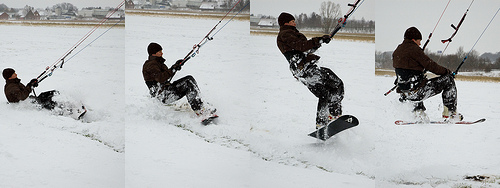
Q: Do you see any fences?
A: No, there are no fences.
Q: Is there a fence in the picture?
A: No, there are no fences.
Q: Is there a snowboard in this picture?
A: Yes, there is a snowboard.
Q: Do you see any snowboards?
A: Yes, there is a snowboard.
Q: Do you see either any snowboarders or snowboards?
A: Yes, there is a snowboard.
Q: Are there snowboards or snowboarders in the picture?
A: Yes, there is a snowboard.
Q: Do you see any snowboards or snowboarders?
A: Yes, there is a snowboard.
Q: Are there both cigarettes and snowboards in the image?
A: No, there is a snowboard but no cigarettes.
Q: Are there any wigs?
A: No, there are no wigs.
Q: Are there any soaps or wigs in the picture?
A: No, there are no wigs or soaps.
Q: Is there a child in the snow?
A: No, there is a snowboard in the snow.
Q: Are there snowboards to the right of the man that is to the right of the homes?
A: Yes, there is a snowboard to the right of the man.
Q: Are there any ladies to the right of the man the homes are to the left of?
A: No, there is a snowboard to the right of the man.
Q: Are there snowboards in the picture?
A: Yes, there is a snowboard.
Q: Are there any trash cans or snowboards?
A: Yes, there is a snowboard.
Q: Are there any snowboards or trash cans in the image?
A: Yes, there is a snowboard.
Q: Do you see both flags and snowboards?
A: No, there is a snowboard but no flags.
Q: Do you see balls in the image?
A: No, there are no balls.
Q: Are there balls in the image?
A: No, there are no balls.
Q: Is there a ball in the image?
A: No, there are no balls.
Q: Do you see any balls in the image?
A: No, there are no balls.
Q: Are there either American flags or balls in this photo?
A: No, there are no balls or American flags.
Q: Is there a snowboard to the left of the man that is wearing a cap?
A: Yes, there is a snowboard to the left of the man.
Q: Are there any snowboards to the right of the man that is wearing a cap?
A: No, the snowboard is to the left of the man.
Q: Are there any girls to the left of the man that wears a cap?
A: No, there is a snowboard to the left of the man.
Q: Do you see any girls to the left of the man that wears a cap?
A: No, there is a snowboard to the left of the man.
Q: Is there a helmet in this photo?
A: No, there are no helmets.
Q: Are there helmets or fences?
A: No, there are no helmets or fences.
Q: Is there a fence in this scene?
A: No, there are no fences.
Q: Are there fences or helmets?
A: No, there are no fences or helmets.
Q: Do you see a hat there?
A: Yes, there is a hat.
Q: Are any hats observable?
A: Yes, there is a hat.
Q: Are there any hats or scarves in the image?
A: Yes, there is a hat.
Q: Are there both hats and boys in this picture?
A: No, there is a hat but no boys.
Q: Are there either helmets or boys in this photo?
A: No, there are no boys or helmets.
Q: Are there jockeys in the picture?
A: No, there are no jockeys.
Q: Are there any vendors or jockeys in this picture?
A: No, there are no jockeys or vendors.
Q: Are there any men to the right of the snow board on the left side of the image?
A: Yes, there is a man to the right of the snowboard.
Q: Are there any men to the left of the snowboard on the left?
A: No, the man is to the right of the snow board.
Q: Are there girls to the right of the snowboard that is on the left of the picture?
A: No, there is a man to the right of the snowboard.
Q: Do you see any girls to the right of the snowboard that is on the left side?
A: No, there is a man to the right of the snowboard.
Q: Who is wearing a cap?
A: The man is wearing a cap.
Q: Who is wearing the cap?
A: The man is wearing a cap.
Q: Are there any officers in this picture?
A: No, there are no officers.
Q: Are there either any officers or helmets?
A: No, there are no officers or helmets.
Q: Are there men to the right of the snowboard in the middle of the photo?
A: Yes, there is a man to the right of the snowboard.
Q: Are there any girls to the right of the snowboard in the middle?
A: No, there is a man to the right of the snowboard.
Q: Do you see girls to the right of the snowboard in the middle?
A: No, there is a man to the right of the snowboard.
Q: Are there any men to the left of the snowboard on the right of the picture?
A: Yes, there is a man to the left of the snow board.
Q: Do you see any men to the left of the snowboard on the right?
A: Yes, there is a man to the left of the snow board.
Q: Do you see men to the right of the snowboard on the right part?
A: No, the man is to the left of the snowboard.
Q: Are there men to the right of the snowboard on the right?
A: No, the man is to the left of the snowboard.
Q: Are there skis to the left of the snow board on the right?
A: No, there is a man to the left of the snowboard.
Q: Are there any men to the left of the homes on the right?
A: Yes, there is a man to the left of the homes.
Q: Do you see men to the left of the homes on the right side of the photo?
A: Yes, there is a man to the left of the homes.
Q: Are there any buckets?
A: No, there are no buckets.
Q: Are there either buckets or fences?
A: No, there are no buckets or fences.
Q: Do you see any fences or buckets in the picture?
A: No, there are no buckets or fences.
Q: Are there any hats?
A: Yes, there is a hat.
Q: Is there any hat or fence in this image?
A: Yes, there is a hat.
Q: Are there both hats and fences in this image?
A: No, there is a hat but no fences.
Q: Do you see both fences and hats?
A: No, there is a hat but no fences.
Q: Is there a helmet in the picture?
A: No, there are no helmets.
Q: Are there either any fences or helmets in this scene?
A: No, there are no helmets or fences.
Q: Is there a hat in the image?
A: Yes, there is a hat.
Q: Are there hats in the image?
A: Yes, there is a hat.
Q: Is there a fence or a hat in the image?
A: Yes, there is a hat.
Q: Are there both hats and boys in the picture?
A: No, there is a hat but no boys.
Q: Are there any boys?
A: No, there are no boys.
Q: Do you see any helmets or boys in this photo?
A: No, there are no boys or helmets.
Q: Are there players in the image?
A: No, there are no players.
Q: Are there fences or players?
A: No, there are no players or fences.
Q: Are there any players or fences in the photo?
A: No, there are no players or fences.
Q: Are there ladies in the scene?
A: No, there are no ladies.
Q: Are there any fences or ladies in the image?
A: No, there are no ladies or fences.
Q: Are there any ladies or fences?
A: No, there are no ladies or fences.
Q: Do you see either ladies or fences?
A: No, there are no ladies or fences.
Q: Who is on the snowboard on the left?
A: The man is on the snowboard.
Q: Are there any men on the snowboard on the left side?
A: Yes, there is a man on the snowboard.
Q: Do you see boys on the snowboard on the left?
A: No, there is a man on the snowboard.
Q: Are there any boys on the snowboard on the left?
A: No, there is a man on the snowboard.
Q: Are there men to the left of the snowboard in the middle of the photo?
A: Yes, there is a man to the left of the snowboard.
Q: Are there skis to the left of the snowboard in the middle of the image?
A: No, there is a man to the left of the snowboard.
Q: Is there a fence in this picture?
A: No, there are no fences.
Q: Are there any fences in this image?
A: No, there are no fences.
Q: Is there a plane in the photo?
A: No, there are no airplanes.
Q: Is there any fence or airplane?
A: No, there are no airplanes or fences.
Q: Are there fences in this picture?
A: No, there are no fences.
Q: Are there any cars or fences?
A: No, there are no fences or cars.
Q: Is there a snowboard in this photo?
A: Yes, there is a snowboard.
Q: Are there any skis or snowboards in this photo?
A: Yes, there is a snowboard.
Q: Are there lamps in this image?
A: No, there are no lamps.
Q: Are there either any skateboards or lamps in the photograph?
A: No, there are no lamps or skateboards.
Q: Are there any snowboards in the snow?
A: Yes, there is a snowboard in the snow.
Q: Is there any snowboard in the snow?
A: Yes, there is a snowboard in the snow.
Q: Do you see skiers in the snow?
A: No, there is a snowboard in the snow.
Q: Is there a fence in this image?
A: No, there are no fences.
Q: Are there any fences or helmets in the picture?
A: No, there are no fences or helmets.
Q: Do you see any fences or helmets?
A: No, there are no fences or helmets.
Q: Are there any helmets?
A: No, there are no helmets.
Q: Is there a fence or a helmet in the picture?
A: No, there are no helmets or fences.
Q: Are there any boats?
A: No, there are no boats.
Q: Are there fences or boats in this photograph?
A: No, there are no boats or fences.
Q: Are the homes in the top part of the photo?
A: Yes, the homes are in the top of the image.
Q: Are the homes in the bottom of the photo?
A: No, the homes are in the top of the image.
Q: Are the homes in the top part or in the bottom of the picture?
A: The homes are in the top of the image.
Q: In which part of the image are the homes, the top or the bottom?
A: The homes are in the top of the image.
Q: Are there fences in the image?
A: No, there are no fences.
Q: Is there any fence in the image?
A: No, there are no fences.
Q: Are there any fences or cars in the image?
A: No, there are no fences or cars.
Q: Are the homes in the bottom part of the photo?
A: No, the homes are in the top of the image.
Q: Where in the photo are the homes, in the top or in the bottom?
A: The homes are in the top of the image.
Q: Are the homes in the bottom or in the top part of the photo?
A: The homes are in the top of the image.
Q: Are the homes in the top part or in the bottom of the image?
A: The homes are in the top of the image.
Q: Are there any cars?
A: No, there are no cars.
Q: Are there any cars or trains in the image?
A: No, there are no cars or trains.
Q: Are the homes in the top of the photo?
A: Yes, the homes are in the top of the image.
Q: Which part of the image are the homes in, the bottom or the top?
A: The homes are in the top of the image.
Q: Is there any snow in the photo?
A: Yes, there is snow.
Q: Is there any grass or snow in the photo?
A: Yes, there is snow.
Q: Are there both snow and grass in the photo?
A: No, there is snow but no grass.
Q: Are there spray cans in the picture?
A: No, there are no spray cans.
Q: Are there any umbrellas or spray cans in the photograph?
A: No, there are no spray cans or umbrellas.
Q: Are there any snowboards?
A: Yes, there is a snowboard.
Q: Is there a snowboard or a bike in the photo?
A: Yes, there is a snowboard.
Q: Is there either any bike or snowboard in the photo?
A: Yes, there is a snowboard.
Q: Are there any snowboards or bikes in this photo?
A: Yes, there is a snowboard.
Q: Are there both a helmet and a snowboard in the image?
A: No, there is a snowboard but no helmets.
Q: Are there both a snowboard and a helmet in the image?
A: No, there is a snowboard but no helmets.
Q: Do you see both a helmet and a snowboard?
A: No, there is a snowboard but no helmets.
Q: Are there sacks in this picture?
A: No, there are no sacks.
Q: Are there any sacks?
A: No, there are no sacks.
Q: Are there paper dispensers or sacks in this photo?
A: No, there are no sacks or paper dispensers.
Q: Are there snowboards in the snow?
A: Yes, there is a snowboard in the snow.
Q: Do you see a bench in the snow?
A: No, there is a snowboard in the snow.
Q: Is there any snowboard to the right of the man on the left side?
A: Yes, there is a snowboard to the right of the man.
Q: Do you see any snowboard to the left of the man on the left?
A: No, the snowboard is to the right of the man.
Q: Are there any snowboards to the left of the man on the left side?
A: No, the snowboard is to the right of the man.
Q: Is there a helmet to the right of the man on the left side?
A: No, there is a snowboard to the right of the man.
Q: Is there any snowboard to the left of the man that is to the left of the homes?
A: Yes, there is a snowboard to the left of the man.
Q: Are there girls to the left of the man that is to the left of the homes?
A: No, there is a snowboard to the left of the man.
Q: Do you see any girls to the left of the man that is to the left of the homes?
A: No, there is a snowboard to the left of the man.